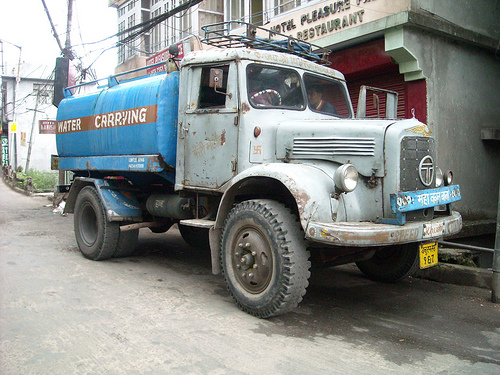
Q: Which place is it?
A: It is a road.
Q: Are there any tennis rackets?
A: No, there are no tennis rackets.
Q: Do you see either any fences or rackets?
A: No, there are no rackets or fences.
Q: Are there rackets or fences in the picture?
A: No, there are no rackets or fences.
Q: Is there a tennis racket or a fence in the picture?
A: No, there are no rackets or fences.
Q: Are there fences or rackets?
A: No, there are no rackets or fences.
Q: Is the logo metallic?
A: Yes, the logo is metallic.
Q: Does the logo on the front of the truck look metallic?
A: Yes, the logo is metallic.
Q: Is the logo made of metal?
A: Yes, the logo is made of metal.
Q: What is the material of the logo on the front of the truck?
A: The logo is made of metal.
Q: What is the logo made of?
A: The logo is made of metal.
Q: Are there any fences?
A: No, there are no fences.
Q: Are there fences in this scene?
A: No, there are no fences.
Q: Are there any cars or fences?
A: No, there are no fences or cars.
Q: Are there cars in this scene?
A: No, there are no cars.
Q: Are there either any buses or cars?
A: No, there are no cars or buses.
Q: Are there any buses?
A: No, there are no buses.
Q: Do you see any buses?
A: No, there are no buses.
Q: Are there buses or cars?
A: No, there are no buses or cars.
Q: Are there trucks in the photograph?
A: Yes, there is a truck.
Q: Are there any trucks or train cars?
A: Yes, there is a truck.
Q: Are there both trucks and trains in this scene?
A: No, there is a truck but no trains.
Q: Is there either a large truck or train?
A: Yes, there is a large truck.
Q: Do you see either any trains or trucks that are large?
A: Yes, the truck is large.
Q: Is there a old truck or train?
A: Yes, there is an old truck.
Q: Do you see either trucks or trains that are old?
A: Yes, the truck is old.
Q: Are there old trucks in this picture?
A: Yes, there is an old truck.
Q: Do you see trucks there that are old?
A: Yes, there is a truck that is old.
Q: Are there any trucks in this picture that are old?
A: Yes, there is a truck that is old.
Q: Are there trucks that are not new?
A: Yes, there is a old truck.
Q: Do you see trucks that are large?
A: Yes, there is a large truck.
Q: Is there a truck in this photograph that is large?
A: Yes, there is a truck that is large.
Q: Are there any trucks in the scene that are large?
A: Yes, there is a truck that is large.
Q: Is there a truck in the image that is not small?
A: Yes, there is a large truck.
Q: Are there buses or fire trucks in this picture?
A: No, there are no buses or fire trucks.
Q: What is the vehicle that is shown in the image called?
A: The vehicle is a truck.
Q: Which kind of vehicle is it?
A: The vehicle is a truck.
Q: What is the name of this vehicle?
A: This is a truck.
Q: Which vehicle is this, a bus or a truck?
A: This is a truck.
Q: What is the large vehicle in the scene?
A: The vehicle is a truck.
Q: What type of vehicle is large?
A: The vehicle is a truck.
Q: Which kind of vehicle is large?
A: The vehicle is a truck.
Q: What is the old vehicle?
A: The vehicle is a truck.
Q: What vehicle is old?
A: The vehicle is a truck.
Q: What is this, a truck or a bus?
A: This is a truck.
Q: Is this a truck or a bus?
A: This is a truck.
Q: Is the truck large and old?
A: Yes, the truck is large and old.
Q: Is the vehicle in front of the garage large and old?
A: Yes, the truck is large and old.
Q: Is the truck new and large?
A: No, the truck is large but old.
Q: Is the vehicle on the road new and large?
A: No, the truck is large but old.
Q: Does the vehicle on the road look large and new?
A: No, the truck is large but old.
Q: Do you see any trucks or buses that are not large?
A: No, there is a truck but it is large.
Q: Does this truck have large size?
A: Yes, the truck is large.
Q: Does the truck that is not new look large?
A: Yes, the truck is large.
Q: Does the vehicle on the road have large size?
A: Yes, the truck is large.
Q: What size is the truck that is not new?
A: The truck is large.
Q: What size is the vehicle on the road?
A: The truck is large.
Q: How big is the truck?
A: The truck is large.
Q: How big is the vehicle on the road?
A: The truck is large.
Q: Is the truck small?
A: No, the truck is large.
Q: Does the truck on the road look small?
A: No, the truck is large.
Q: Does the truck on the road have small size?
A: No, the truck is large.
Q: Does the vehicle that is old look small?
A: No, the truck is large.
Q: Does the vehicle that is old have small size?
A: No, the truck is large.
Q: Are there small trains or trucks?
A: No, there is a truck but it is large.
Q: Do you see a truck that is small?
A: No, there is a truck but it is large.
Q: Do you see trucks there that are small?
A: No, there is a truck but it is large.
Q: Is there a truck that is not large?
A: No, there is a truck but it is large.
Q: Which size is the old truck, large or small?
A: The truck is large.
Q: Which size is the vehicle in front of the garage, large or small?
A: The truck is large.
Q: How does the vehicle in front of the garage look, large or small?
A: The truck is large.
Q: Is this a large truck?
A: Yes, this is a large truck.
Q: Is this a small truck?
A: No, this is a large truck.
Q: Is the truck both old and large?
A: Yes, the truck is old and large.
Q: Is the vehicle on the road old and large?
A: Yes, the truck is old and large.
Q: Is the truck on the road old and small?
A: No, the truck is old but large.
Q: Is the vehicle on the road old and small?
A: No, the truck is old but large.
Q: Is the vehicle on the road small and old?
A: No, the truck is old but large.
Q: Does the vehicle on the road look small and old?
A: No, the truck is old but large.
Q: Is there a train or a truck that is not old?
A: No, there is a truck but it is old.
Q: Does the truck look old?
A: Yes, the truck is old.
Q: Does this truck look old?
A: Yes, the truck is old.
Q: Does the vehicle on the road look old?
A: Yes, the truck is old.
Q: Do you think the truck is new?
A: No, the truck is old.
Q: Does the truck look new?
A: No, the truck is old.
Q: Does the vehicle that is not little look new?
A: No, the truck is old.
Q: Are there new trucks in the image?
A: No, there is a truck but it is old.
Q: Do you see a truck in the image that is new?
A: No, there is a truck but it is old.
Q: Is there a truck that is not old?
A: No, there is a truck but it is old.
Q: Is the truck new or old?
A: The truck is old.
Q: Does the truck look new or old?
A: The truck is old.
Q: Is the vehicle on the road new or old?
A: The truck is old.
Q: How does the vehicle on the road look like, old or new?
A: The truck is old.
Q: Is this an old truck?
A: Yes, this is an old truck.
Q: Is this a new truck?
A: No, this is an old truck.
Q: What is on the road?
A: The truck is on the road.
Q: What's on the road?
A: The truck is on the road.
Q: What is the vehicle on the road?
A: The vehicle is a truck.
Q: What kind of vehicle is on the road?
A: The vehicle is a truck.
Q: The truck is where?
A: The truck is on the road.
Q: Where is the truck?
A: The truck is on the road.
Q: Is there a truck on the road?
A: Yes, there is a truck on the road.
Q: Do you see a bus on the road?
A: No, there is a truck on the road.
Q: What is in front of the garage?
A: The truck is in front of the garage.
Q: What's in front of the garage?
A: The truck is in front of the garage.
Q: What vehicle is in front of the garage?
A: The vehicle is a truck.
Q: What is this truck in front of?
A: The truck is in front of the garage.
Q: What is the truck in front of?
A: The truck is in front of the garage.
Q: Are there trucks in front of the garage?
A: Yes, there is a truck in front of the garage.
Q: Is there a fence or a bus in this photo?
A: No, there are no fences or buses.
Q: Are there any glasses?
A: No, there are no glasses.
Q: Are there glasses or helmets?
A: No, there are no glasses or helmets.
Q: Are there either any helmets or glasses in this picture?
A: No, there are no glasses or helmets.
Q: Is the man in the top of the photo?
A: Yes, the man is in the top of the image.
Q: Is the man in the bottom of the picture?
A: No, the man is in the top of the image.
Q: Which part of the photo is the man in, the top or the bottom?
A: The man is in the top of the image.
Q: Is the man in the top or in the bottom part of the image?
A: The man is in the top of the image.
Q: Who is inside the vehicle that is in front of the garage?
A: The man is inside the truck.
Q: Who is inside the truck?
A: The man is inside the truck.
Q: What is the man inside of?
A: The man is inside the truck.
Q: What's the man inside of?
A: The man is inside the truck.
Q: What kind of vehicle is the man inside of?
A: The man is inside the truck.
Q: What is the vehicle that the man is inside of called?
A: The vehicle is a truck.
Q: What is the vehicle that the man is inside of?
A: The vehicle is a truck.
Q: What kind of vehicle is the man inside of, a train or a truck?
A: The man is inside a truck.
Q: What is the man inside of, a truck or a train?
A: The man is inside a truck.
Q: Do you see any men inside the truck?
A: Yes, there is a man inside the truck.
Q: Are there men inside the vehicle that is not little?
A: Yes, there is a man inside the truck.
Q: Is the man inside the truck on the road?
A: Yes, the man is inside the truck.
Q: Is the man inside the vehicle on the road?
A: Yes, the man is inside the truck.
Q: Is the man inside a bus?
A: No, the man is inside the truck.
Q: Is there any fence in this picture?
A: No, there are no fences.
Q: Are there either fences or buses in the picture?
A: No, there are no fences or buses.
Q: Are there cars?
A: No, there are no cars.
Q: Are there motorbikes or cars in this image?
A: No, there are no cars or motorbikes.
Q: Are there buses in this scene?
A: No, there are no buses.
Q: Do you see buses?
A: No, there are no buses.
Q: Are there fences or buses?
A: No, there are no buses or fences.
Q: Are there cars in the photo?
A: No, there are no cars.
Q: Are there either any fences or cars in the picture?
A: No, there are no cars or fences.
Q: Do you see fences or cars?
A: No, there are no cars or fences.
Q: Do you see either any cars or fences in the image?
A: No, there are no cars or fences.